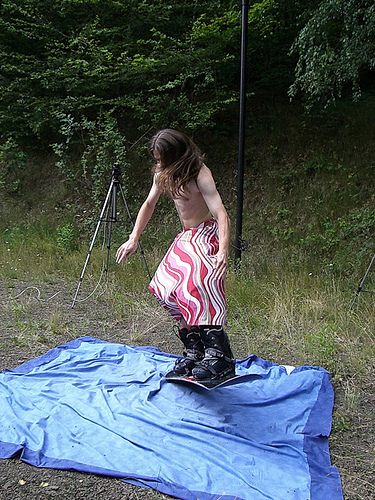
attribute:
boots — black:
[174, 327, 249, 377]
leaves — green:
[40, 43, 195, 90]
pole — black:
[222, 8, 261, 262]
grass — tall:
[13, 241, 109, 286]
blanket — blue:
[11, 330, 345, 497]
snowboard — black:
[176, 368, 213, 397]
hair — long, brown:
[147, 129, 209, 201]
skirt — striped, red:
[143, 226, 245, 339]